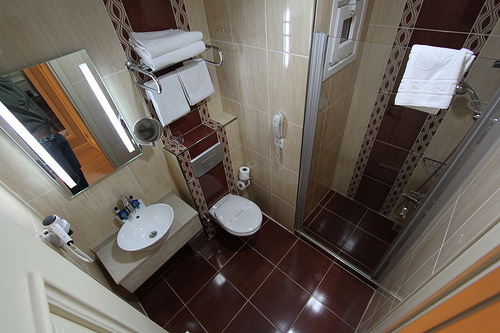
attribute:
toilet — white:
[202, 187, 265, 239]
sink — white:
[111, 192, 176, 259]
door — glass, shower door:
[285, 1, 499, 283]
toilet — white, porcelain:
[208, 191, 265, 234]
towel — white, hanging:
[391, 44, 477, 114]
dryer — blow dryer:
[35, 212, 98, 266]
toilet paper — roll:
[240, 166, 253, 181]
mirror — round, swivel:
[133, 115, 168, 145]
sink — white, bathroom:
[108, 197, 177, 252]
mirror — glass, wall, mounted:
[0, 50, 142, 200]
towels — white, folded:
[122, 24, 219, 127]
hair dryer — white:
[41, 213, 94, 263]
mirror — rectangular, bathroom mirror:
[3, 57, 133, 191]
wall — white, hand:
[247, 166, 328, 204]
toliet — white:
[195, 185, 301, 251]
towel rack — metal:
[123, 34, 232, 97]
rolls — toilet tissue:
[229, 156, 255, 195]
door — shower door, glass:
[271, 40, 466, 331]